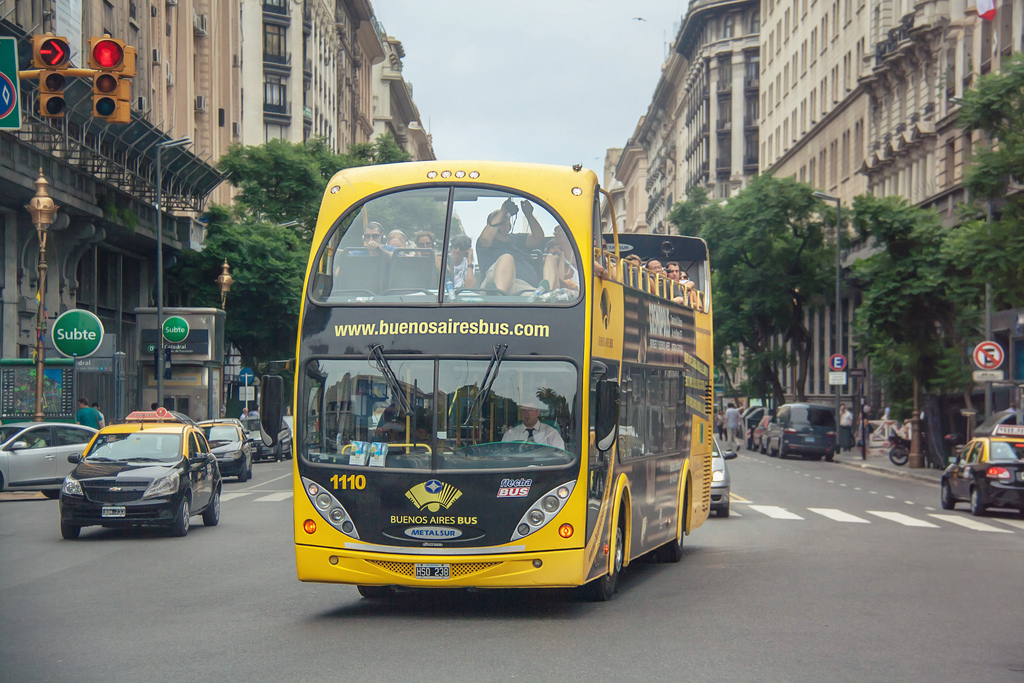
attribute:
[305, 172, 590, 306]
windshield — upper deck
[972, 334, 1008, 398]
street signs — traffic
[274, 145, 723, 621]
bus — yellow, double decker, tour, shiny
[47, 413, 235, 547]
car — black, yellow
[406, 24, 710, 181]
clouds — white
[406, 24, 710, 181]
sky — blue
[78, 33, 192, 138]
light — red, signal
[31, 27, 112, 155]
light — red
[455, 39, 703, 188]
clouds — white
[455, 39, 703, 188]
sky — blue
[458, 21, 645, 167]
clouds — white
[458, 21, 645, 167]
sky — blue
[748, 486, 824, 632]
street — grey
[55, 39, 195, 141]
signal — traffic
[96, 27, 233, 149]
light — red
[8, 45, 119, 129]
arrow — red